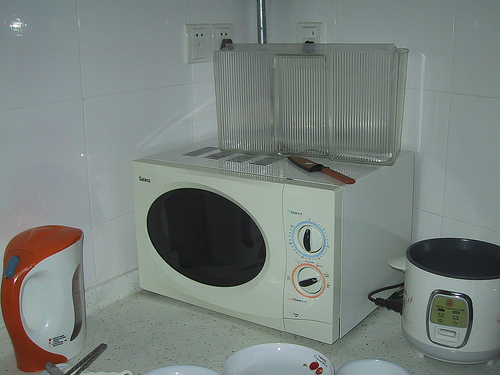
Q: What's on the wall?
A: The outlet is on the wall.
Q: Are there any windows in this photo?
A: Yes, there is a window.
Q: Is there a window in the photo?
A: Yes, there is a window.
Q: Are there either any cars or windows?
A: Yes, there is a window.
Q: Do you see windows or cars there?
A: Yes, there is a window.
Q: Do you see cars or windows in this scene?
A: Yes, there is a window.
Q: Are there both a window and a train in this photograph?
A: No, there is a window but no trains.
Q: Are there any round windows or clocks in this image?
A: Yes, there is a round window.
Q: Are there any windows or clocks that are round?
A: Yes, the window is round.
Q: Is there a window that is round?
A: Yes, there is a round window.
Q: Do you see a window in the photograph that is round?
A: Yes, there is a window that is round.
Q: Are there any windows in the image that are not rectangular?
A: Yes, there is a round window.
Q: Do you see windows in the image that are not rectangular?
A: Yes, there is a round window.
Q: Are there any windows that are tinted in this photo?
A: Yes, there is a tinted window.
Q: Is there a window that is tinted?
A: Yes, there is a window that is tinted.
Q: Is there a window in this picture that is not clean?
A: Yes, there is a tinted window.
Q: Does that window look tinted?
A: Yes, the window is tinted.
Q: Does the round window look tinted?
A: Yes, the window is tinted.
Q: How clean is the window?
A: The window is tinted.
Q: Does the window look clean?
A: No, the window is tinted.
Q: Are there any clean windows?
A: No, there is a window but it is tinted.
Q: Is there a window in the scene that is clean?
A: No, there is a window but it is tinted.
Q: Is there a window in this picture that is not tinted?
A: No, there is a window but it is tinted.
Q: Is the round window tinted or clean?
A: The window is tinted.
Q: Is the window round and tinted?
A: Yes, the window is round and tinted.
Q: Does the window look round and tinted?
A: Yes, the window is round and tinted.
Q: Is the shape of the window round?
A: Yes, the window is round.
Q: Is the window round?
A: Yes, the window is round.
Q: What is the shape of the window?
A: The window is round.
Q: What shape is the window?
A: The window is round.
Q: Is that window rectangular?
A: No, the window is round.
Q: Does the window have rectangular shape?
A: No, the window is round.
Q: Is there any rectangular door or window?
A: No, there is a window but it is round.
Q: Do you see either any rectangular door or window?
A: No, there is a window but it is round.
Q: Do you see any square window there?
A: No, there is a window but it is round.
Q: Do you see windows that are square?
A: No, there is a window but it is round.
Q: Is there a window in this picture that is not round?
A: No, there is a window but it is round.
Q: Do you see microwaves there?
A: Yes, there is a microwave.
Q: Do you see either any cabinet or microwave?
A: Yes, there is a microwave.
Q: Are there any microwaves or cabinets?
A: Yes, there is a microwave.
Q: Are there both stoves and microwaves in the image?
A: No, there is a microwave but no stoves.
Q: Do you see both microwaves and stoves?
A: No, there is a microwave but no stoves.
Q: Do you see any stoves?
A: No, there are no stoves.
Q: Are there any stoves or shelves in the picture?
A: No, there are no stoves or shelves.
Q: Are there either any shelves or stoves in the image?
A: No, there are no stoves or shelves.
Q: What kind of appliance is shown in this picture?
A: The appliance is a microwave.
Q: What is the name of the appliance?
A: The appliance is a microwave.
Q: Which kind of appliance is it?
A: The appliance is a microwave.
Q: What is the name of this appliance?
A: That is a microwave.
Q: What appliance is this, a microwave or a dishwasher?
A: That is a microwave.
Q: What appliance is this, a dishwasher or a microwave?
A: That is a microwave.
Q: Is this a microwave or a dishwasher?
A: This is a microwave.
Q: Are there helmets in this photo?
A: No, there are no helmets.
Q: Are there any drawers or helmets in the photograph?
A: No, there are no helmets or drawers.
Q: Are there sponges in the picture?
A: No, there are no sponges.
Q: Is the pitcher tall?
A: Yes, the pitcher is tall.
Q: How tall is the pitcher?
A: The pitcher is tall.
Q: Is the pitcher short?
A: No, the pitcher is tall.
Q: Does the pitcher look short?
A: No, the pitcher is tall.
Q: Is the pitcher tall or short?
A: The pitcher is tall.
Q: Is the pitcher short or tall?
A: The pitcher is tall.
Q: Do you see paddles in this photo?
A: No, there are no paddles.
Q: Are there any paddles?
A: No, there are no paddles.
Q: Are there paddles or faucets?
A: No, there are no paddles or faucets.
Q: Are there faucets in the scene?
A: No, there are no faucets.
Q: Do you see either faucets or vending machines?
A: No, there are no faucets or vending machines.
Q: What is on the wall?
A: The electrical outlet is on the wall.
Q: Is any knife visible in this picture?
A: Yes, there is a knife.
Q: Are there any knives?
A: Yes, there is a knife.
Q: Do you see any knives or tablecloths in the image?
A: Yes, there is a knife.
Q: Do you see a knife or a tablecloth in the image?
A: Yes, there is a knife.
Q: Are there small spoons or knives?
A: Yes, there is a small knife.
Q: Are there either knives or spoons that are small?
A: Yes, the knife is small.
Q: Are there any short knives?
A: Yes, there is a short knife.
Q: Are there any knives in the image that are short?
A: Yes, there is a knife that is short.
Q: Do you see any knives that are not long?
A: Yes, there is a short knife.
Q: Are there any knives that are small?
A: Yes, there is a small knife.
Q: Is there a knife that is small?
A: Yes, there is a knife that is small.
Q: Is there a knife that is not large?
A: Yes, there is a small knife.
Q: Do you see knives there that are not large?
A: Yes, there is a small knife.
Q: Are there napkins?
A: No, there are no napkins.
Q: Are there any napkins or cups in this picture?
A: No, there are no napkins or cups.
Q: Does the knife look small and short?
A: Yes, the knife is small and short.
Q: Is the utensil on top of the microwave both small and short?
A: Yes, the knife is small and short.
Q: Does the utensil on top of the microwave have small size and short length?
A: Yes, the knife is small and short.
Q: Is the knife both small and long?
A: No, the knife is small but short.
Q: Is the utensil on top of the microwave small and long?
A: No, the knife is small but short.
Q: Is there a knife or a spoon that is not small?
A: No, there is a knife but it is small.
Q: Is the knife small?
A: Yes, the knife is small.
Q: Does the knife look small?
A: Yes, the knife is small.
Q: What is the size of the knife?
A: The knife is small.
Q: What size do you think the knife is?
A: The knife is small.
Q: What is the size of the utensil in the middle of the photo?
A: The knife is small.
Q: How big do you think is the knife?
A: The knife is small.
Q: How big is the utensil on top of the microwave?
A: The knife is small.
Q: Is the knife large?
A: No, the knife is small.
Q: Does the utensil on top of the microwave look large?
A: No, the knife is small.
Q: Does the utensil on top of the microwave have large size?
A: No, the knife is small.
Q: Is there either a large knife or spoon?
A: No, there is a knife but it is small.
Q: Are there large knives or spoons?
A: No, there is a knife but it is small.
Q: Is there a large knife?
A: No, there is a knife but it is small.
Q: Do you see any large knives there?
A: No, there is a knife but it is small.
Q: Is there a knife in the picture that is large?
A: No, there is a knife but it is small.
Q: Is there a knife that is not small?
A: No, there is a knife but it is small.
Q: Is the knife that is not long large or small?
A: The knife is small.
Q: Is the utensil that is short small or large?
A: The knife is small.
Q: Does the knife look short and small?
A: Yes, the knife is short and small.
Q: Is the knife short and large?
A: No, the knife is short but small.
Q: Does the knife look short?
A: Yes, the knife is short.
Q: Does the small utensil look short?
A: Yes, the knife is short.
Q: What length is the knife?
A: The knife is short.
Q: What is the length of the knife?
A: The knife is short.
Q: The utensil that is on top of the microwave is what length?
A: The knife is short.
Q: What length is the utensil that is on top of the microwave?
A: The knife is short.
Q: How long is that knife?
A: The knife is short.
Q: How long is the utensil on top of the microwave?
A: The knife is short.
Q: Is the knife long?
A: No, the knife is short.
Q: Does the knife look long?
A: No, the knife is short.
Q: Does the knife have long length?
A: No, the knife is short.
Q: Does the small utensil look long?
A: No, the knife is short.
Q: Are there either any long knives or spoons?
A: No, there is a knife but it is short.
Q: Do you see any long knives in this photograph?
A: No, there is a knife but it is short.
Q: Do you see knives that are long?
A: No, there is a knife but it is short.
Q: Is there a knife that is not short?
A: No, there is a knife but it is short.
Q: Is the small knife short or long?
A: The knife is short.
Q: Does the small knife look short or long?
A: The knife is short.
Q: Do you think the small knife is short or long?
A: The knife is short.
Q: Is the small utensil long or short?
A: The knife is short.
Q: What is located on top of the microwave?
A: The knife is on top of the microwave.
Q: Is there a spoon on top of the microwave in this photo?
A: No, there is a knife on top of the microwave.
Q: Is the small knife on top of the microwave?
A: Yes, the knife is on top of the microwave.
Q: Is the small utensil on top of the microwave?
A: Yes, the knife is on top of the microwave.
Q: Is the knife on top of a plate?
A: No, the knife is on top of the microwave.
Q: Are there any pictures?
A: No, there are no pictures.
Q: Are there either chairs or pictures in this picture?
A: No, there are no pictures or chairs.